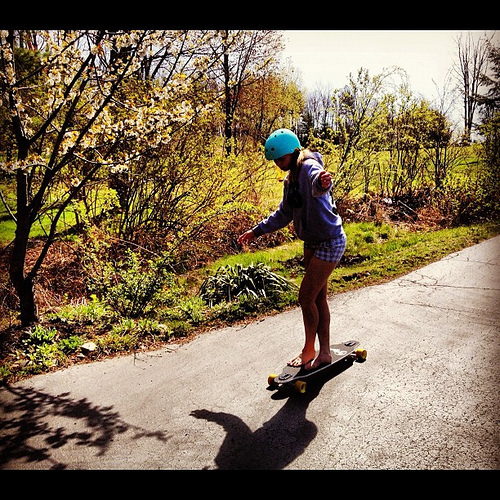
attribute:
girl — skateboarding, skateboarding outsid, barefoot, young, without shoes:
[236, 126, 348, 369]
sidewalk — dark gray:
[1, 230, 497, 470]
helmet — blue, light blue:
[263, 129, 303, 156]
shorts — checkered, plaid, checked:
[302, 234, 348, 263]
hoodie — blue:
[252, 152, 345, 241]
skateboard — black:
[268, 339, 368, 396]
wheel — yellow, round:
[354, 345, 369, 362]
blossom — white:
[73, 177, 82, 190]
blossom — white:
[109, 164, 129, 174]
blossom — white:
[157, 134, 171, 144]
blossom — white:
[173, 101, 193, 125]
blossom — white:
[135, 117, 157, 134]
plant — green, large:
[197, 261, 301, 305]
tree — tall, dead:
[454, 31, 496, 140]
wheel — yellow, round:
[294, 378, 309, 397]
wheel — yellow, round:
[267, 373, 278, 386]